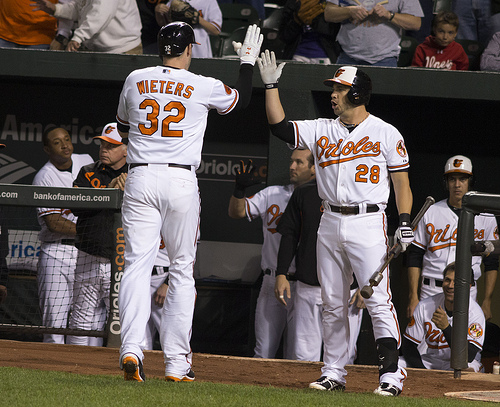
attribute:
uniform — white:
[113, 63, 242, 373]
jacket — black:
[68, 160, 126, 260]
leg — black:
[341, 215, 408, 402]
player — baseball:
[226, 145, 316, 359]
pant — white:
[322, 213, 396, 383]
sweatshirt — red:
[408, 36, 479, 76]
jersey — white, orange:
[290, 112, 405, 211]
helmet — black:
[159, 20, 196, 58]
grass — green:
[8, 373, 233, 405]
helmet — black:
[158, 20, 200, 46]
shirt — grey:
[331, 4, 426, 64]